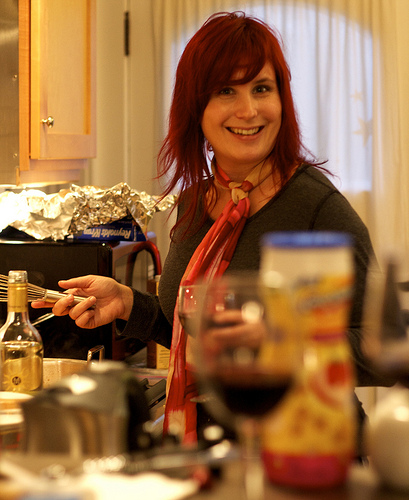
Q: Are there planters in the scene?
A: No, there are no planters.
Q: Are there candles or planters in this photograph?
A: No, there are no planters or candles.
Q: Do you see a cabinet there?
A: Yes, there is a cabinet.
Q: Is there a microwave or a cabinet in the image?
A: Yes, there is a cabinet.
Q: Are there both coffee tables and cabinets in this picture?
A: No, there is a cabinet but no coffee tables.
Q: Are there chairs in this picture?
A: No, there are no chairs.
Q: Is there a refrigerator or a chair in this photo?
A: No, there are no chairs or refrigerators.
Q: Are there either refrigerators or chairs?
A: No, there are no chairs or refrigerators.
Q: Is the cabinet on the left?
A: Yes, the cabinet is on the left of the image.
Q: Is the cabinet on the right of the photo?
A: No, the cabinet is on the left of the image.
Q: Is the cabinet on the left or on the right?
A: The cabinet is on the left of the image.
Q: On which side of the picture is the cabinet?
A: The cabinet is on the left of the image.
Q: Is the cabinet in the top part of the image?
A: Yes, the cabinet is in the top of the image.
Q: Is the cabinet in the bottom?
A: No, the cabinet is in the top of the image.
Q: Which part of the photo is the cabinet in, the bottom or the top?
A: The cabinet is in the top of the image.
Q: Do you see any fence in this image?
A: No, there are no fences.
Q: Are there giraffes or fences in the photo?
A: No, there are no fences or giraffes.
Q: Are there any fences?
A: No, there are no fences.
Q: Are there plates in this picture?
A: No, there are no plates.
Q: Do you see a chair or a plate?
A: No, there are no plates or chairs.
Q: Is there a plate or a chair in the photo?
A: No, there are no plates or chairs.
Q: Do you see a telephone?
A: No, there are no phones.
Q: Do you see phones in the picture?
A: No, there are no phones.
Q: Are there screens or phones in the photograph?
A: No, there are no phones or screens.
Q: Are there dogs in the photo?
A: No, there are no dogs.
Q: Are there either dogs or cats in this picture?
A: No, there are no dogs or cats.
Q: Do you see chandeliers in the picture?
A: No, there are no chandeliers.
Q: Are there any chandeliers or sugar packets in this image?
A: No, there are no chandeliers or sugar packets.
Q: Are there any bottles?
A: Yes, there is a bottle.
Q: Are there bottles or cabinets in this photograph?
A: Yes, there is a bottle.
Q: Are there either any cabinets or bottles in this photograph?
A: Yes, there is a bottle.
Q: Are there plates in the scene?
A: No, there are no plates.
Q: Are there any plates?
A: No, there are no plates.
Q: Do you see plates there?
A: No, there are no plates.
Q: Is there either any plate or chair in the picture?
A: No, there are no plates or chairs.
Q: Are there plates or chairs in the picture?
A: No, there are no plates or chairs.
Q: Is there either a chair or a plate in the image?
A: No, there are no plates or chairs.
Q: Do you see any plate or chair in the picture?
A: No, there are no plates or chairs.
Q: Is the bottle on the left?
A: Yes, the bottle is on the left of the image.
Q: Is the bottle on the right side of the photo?
A: No, the bottle is on the left of the image.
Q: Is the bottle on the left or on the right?
A: The bottle is on the left of the image.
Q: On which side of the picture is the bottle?
A: The bottle is on the left of the image.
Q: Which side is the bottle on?
A: The bottle is on the left of the image.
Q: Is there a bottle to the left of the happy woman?
A: Yes, there is a bottle to the left of the woman.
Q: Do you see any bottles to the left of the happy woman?
A: Yes, there is a bottle to the left of the woman.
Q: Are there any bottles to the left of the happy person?
A: Yes, there is a bottle to the left of the woman.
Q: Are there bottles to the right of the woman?
A: No, the bottle is to the left of the woman.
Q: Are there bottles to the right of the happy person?
A: No, the bottle is to the left of the woman.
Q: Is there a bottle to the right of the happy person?
A: No, the bottle is to the left of the woman.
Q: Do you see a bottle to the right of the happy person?
A: No, the bottle is to the left of the woman.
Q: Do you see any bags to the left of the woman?
A: No, there is a bottle to the left of the woman.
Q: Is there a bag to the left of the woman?
A: No, there is a bottle to the left of the woman.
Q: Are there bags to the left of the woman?
A: No, there is a bottle to the left of the woman.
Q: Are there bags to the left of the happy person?
A: No, there is a bottle to the left of the woman.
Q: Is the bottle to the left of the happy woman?
A: Yes, the bottle is to the left of the woman.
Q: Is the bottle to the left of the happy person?
A: Yes, the bottle is to the left of the woman.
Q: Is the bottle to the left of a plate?
A: No, the bottle is to the left of the woman.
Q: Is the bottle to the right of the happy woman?
A: No, the bottle is to the left of the woman.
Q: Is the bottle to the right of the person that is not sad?
A: No, the bottle is to the left of the woman.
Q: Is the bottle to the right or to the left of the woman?
A: The bottle is to the left of the woman.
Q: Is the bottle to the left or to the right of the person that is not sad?
A: The bottle is to the left of the woman.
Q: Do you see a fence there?
A: No, there are no fences.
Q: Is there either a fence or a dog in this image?
A: No, there are no fences or dogs.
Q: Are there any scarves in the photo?
A: Yes, there is a scarf.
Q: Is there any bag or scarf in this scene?
A: Yes, there is a scarf.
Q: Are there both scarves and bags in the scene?
A: No, there is a scarf but no bags.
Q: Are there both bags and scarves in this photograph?
A: No, there is a scarf but no bags.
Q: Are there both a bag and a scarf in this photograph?
A: No, there is a scarf but no bags.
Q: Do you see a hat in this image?
A: No, there are no hats.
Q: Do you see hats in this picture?
A: No, there are no hats.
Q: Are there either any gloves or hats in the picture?
A: No, there are no hats or gloves.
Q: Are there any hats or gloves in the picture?
A: No, there are no hats or gloves.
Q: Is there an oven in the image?
A: Yes, there is an oven.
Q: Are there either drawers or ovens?
A: Yes, there is an oven.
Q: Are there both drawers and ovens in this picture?
A: No, there is an oven but no drawers.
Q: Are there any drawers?
A: No, there are no drawers.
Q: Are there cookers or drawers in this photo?
A: No, there are no drawers or cookers.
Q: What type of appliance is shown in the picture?
A: The appliance is an oven.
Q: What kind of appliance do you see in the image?
A: The appliance is an oven.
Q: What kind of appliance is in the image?
A: The appliance is an oven.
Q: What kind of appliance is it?
A: The appliance is an oven.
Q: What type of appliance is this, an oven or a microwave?
A: That is an oven.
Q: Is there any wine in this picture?
A: Yes, there is wine.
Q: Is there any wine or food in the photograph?
A: Yes, there is wine.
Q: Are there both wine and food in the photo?
A: No, there is wine but no food.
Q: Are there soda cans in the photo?
A: No, there are no soda cans.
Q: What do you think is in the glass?
A: The wine is in the glass.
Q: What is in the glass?
A: The wine is in the glass.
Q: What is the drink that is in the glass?
A: The drink is wine.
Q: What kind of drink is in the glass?
A: The drink is wine.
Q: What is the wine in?
A: The wine is in the glass.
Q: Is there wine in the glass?
A: Yes, there is wine in the glass.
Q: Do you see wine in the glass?
A: Yes, there is wine in the glass.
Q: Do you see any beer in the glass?
A: No, there is wine in the glass.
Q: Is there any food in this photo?
A: No, there is no food.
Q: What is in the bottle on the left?
A: The oil is in the bottle.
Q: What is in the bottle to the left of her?
A: The oil is in the bottle.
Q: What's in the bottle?
A: The oil is in the bottle.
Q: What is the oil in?
A: The oil is in the bottle.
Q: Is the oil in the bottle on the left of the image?
A: Yes, the oil is in the bottle.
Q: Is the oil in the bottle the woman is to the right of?
A: Yes, the oil is in the bottle.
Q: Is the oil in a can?
A: No, the oil is in the bottle.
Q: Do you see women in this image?
A: Yes, there is a woman.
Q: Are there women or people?
A: Yes, there is a woman.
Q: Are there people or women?
A: Yes, there is a woman.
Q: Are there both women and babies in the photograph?
A: No, there is a woman but no babies.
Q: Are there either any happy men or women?
A: Yes, there is a happy woman.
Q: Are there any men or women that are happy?
A: Yes, the woman is happy.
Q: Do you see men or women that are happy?
A: Yes, the woman is happy.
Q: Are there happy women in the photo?
A: Yes, there is a happy woman.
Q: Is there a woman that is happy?
A: Yes, there is a woman that is happy.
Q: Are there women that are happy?
A: Yes, there is a woman that is happy.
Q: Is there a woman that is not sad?
A: Yes, there is a happy woman.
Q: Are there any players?
A: No, there are no players.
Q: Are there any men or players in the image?
A: No, there are no players or men.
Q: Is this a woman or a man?
A: This is a woman.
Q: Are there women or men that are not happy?
A: No, there is a woman but she is happy.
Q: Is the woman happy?
A: Yes, the woman is happy.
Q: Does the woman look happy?
A: Yes, the woman is happy.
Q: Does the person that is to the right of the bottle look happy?
A: Yes, the woman is happy.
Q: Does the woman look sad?
A: No, the woman is happy.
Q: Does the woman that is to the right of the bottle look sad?
A: No, the woman is happy.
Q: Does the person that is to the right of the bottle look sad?
A: No, the woman is happy.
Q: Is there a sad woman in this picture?
A: No, there is a woman but she is happy.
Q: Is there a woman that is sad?
A: No, there is a woman but she is happy.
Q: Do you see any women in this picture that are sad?
A: No, there is a woman but she is happy.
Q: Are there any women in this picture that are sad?
A: No, there is a woman but she is happy.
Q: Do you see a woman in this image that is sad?
A: No, there is a woman but she is happy.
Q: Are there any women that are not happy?
A: No, there is a woman but she is happy.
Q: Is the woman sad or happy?
A: The woman is happy.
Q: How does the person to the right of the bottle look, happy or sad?
A: The woman is happy.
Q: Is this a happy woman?
A: Yes, this is a happy woman.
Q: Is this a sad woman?
A: No, this is a happy woman.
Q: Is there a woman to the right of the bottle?
A: Yes, there is a woman to the right of the bottle.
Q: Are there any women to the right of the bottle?
A: Yes, there is a woman to the right of the bottle.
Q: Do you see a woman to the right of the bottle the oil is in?
A: Yes, there is a woman to the right of the bottle.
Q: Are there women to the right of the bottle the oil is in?
A: Yes, there is a woman to the right of the bottle.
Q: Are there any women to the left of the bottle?
A: No, the woman is to the right of the bottle.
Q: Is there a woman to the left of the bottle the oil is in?
A: No, the woman is to the right of the bottle.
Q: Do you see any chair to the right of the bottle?
A: No, there is a woman to the right of the bottle.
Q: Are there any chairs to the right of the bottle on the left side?
A: No, there is a woman to the right of the bottle.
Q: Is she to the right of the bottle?
A: Yes, the woman is to the right of the bottle.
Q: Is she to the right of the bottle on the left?
A: Yes, the woman is to the right of the bottle.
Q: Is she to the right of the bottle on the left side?
A: Yes, the woman is to the right of the bottle.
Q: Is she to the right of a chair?
A: No, the woman is to the right of the bottle.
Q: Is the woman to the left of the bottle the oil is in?
A: No, the woman is to the right of the bottle.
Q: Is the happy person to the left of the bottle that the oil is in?
A: No, the woman is to the right of the bottle.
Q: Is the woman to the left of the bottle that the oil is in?
A: No, the woman is to the right of the bottle.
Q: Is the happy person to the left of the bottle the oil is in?
A: No, the woman is to the right of the bottle.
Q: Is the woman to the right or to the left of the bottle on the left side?
A: The woman is to the right of the bottle.